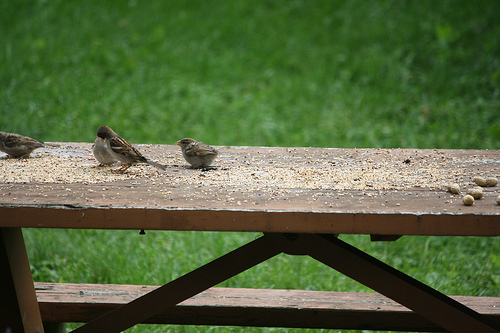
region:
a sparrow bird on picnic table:
[171, 130, 221, 188]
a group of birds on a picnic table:
[1, 105, 233, 206]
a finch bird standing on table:
[93, 117, 165, 173]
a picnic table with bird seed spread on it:
[0, 137, 499, 204]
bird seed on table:
[221, 139, 496, 206]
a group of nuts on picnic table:
[443, 166, 494, 206]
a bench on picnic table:
[0, 265, 499, 322]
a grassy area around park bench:
[0, 0, 497, 292]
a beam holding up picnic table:
[1, 227, 486, 332]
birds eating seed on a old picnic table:
[1, 118, 426, 206]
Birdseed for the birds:
[256, 148, 368, 201]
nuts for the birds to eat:
[443, 163, 498, 207]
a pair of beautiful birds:
[82, 122, 164, 180]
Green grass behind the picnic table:
[173, 63, 324, 132]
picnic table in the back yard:
[102, 176, 435, 331]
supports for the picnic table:
[231, 227, 374, 272]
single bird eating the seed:
[163, 127, 225, 177]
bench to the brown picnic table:
[232, 275, 317, 331]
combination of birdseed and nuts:
[331, 161, 498, 208]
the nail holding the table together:
[128, 223, 164, 245]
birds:
[1, 117, 222, 175]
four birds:
[0, 119, 238, 180]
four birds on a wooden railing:
[0, 122, 497, 234]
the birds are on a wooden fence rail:
[3, 126, 499, 221]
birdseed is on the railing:
[5, 128, 499, 223]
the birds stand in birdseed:
[3, 117, 290, 212]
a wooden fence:
[5, 132, 497, 331]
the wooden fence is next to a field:
[5, 131, 498, 331]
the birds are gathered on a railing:
[5, 117, 233, 181]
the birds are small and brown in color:
[3, 121, 226, 179]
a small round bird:
[172, 126, 230, 179]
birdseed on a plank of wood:
[38, 108, 465, 234]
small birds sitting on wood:
[6, 113, 251, 194]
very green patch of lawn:
[24, 14, 488, 269]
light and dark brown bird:
[77, 120, 193, 205]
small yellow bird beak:
[167, 124, 194, 162]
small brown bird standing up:
[93, 124, 173, 195]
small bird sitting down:
[170, 118, 234, 175]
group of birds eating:
[2, 101, 252, 238]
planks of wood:
[19, 101, 464, 319]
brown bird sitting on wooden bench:
[178, 136, 216, 168]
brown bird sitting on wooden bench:
[91, 125, 158, 177]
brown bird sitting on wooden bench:
[3, 126, 48, 160]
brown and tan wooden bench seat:
[11, 172, 441, 219]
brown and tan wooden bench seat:
[239, 154, 444, 206]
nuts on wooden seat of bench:
[431, 164, 499, 213]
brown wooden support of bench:
[226, 235, 386, 325]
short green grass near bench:
[33, 234, 197, 268]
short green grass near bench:
[12, 5, 194, 114]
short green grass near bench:
[178, 8, 476, 131]